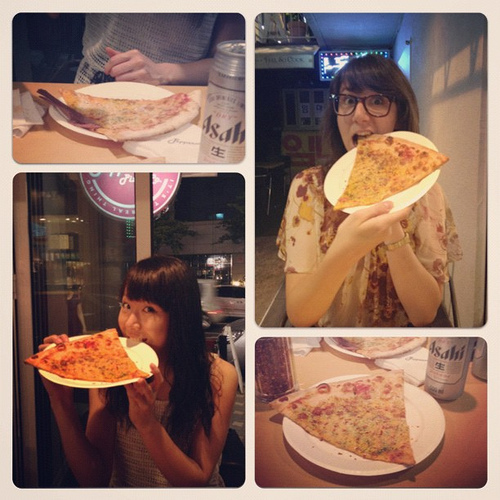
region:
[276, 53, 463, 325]
A woman holding a plate of pizza.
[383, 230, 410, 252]
The woman is wearing a watch.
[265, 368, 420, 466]
A large triangular slice of pizza.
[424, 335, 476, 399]
A can of beer.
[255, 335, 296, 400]
A container of crushed red peppers.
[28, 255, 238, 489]
A woman biting the plate a pizza is on.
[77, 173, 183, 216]
A large business sign.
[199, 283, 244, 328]
A vehicle driving past.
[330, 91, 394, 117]
The woman is wearing glasses.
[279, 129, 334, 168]
Korean lettering on a sign.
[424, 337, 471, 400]
gray aluminum can of Asahi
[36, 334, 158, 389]
white paper plate the woman is biting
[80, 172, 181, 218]
bottom of red round sign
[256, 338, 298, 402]
part of red pepper shaker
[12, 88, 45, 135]
stack of three white paper napkins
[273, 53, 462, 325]
woman with glasses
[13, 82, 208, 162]
brown wooden table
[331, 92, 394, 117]
glasses with brown frames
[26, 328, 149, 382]
large slice of pepperoni pizza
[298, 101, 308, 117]
large white sign with a blue B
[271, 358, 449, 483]
Plate on the table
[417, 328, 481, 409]
Can on the table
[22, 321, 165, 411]
Plate in woman's hand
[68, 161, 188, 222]
Sign in the background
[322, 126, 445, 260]
Plate in woman's hand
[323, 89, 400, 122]
Eyeglasses on woman's face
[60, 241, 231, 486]
Woman wearing a white tanktop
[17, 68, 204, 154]
Plate on the table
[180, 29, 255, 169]
Can on the table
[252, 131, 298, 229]
Table in the background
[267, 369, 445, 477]
Slice of pizza on a plate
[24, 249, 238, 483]
Girl biting a plate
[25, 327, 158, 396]
Slice of pizza on a plate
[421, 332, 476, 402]
Can of beer on the table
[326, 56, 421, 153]
Girl wearing glasses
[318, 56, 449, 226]
Girl biting pizza crust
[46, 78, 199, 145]
Pizza on a plate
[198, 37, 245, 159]
Can of beer on the table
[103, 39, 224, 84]
Arm resting on table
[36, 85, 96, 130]
Knife on the plate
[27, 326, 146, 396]
huge slice of pizza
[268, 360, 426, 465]
huge slice of pizza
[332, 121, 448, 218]
huge slice of pizza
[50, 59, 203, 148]
huge slice of pizza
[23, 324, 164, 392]
slice of pizza on white paper plate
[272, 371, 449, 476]
slice of pizza on white paper plate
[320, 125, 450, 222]
slice of pizza on white paper plate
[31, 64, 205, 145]
slice of pizza on white paper plate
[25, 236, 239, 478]
woman holding huge slice of pizza on plate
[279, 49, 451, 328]
woman holding huge slice of pizza on plate